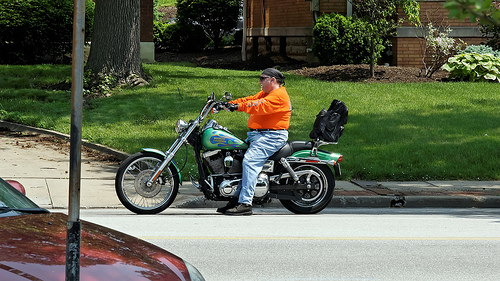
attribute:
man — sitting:
[230, 59, 292, 191]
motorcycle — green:
[122, 93, 339, 215]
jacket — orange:
[226, 86, 292, 127]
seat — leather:
[277, 138, 313, 160]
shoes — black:
[217, 199, 253, 218]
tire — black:
[277, 160, 343, 211]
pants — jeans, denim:
[241, 129, 286, 201]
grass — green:
[23, 63, 496, 181]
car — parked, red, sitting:
[4, 176, 195, 279]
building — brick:
[244, 3, 495, 63]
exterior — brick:
[243, 1, 495, 76]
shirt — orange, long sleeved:
[240, 88, 292, 129]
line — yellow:
[140, 229, 493, 244]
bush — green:
[314, 16, 370, 63]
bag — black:
[314, 96, 353, 145]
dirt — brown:
[288, 62, 436, 85]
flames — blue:
[214, 128, 244, 150]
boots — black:
[220, 192, 254, 218]